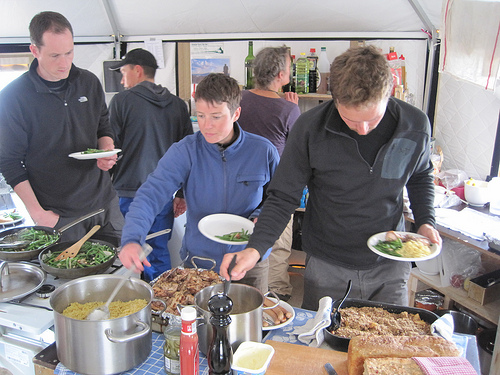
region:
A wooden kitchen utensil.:
[49, 225, 101, 262]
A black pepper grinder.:
[207, 286, 232, 373]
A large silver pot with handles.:
[49, 274, 154, 374]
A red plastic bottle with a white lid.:
[178, 305, 198, 374]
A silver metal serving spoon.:
[89, 244, 154, 328]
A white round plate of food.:
[365, 227, 440, 262]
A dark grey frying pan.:
[40, 225, 174, 276]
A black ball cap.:
[109, 46, 160, 71]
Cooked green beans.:
[46, 240, 113, 271]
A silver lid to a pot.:
[0, 258, 44, 305]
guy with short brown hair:
[281, 45, 448, 295]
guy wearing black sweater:
[278, 51, 450, 298]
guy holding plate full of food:
[281, 45, 445, 308]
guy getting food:
[201, 43, 437, 355]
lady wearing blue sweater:
[120, 79, 275, 279]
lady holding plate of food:
[120, 73, 278, 300]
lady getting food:
[58, 63, 290, 330]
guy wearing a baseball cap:
[103, 36, 184, 111]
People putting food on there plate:
[5, 14, 497, 374]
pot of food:
[53, 266, 160, 373]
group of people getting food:
[1, 11, 495, 328]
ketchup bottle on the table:
[168, 298, 204, 374]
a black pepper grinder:
[205, 288, 247, 374]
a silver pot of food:
[47, 273, 154, 373]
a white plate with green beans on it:
[197, 210, 261, 247]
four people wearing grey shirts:
[10, 10, 456, 307]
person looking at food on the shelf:
[236, 42, 418, 102]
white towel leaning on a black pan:
[297, 293, 337, 350]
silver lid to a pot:
[0, 252, 46, 307]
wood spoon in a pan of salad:
[40, 220, 119, 272]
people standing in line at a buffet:
[1, 13, 443, 336]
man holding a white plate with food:
[368, 215, 438, 265]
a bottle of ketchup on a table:
[181, 306, 201, 373]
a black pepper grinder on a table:
[208, 288, 232, 374]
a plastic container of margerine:
[232, 335, 274, 373]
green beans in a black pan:
[41, 239, 112, 274]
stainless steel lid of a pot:
[0, 260, 45, 302]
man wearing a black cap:
[109, 45, 159, 75]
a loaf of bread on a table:
[346, 338, 466, 374]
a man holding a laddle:
[210, 247, 265, 294]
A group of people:
[3, 11, 455, 306]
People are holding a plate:
[44, 130, 456, 273]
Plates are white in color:
[61, 140, 452, 278]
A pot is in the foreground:
[35, 270, 160, 373]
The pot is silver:
[43, 266, 168, 372]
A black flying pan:
[1, 215, 66, 263]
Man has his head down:
[311, 67, 407, 153]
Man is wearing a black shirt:
[243, 98, 445, 290]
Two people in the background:
[96, 40, 301, 150]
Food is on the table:
[3, 223, 463, 373]